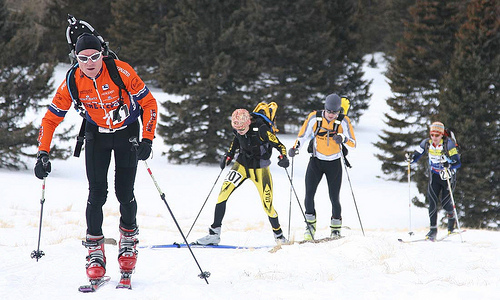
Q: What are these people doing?
A: Skiing.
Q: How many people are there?
A: 4.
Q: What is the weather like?
A: Cold.